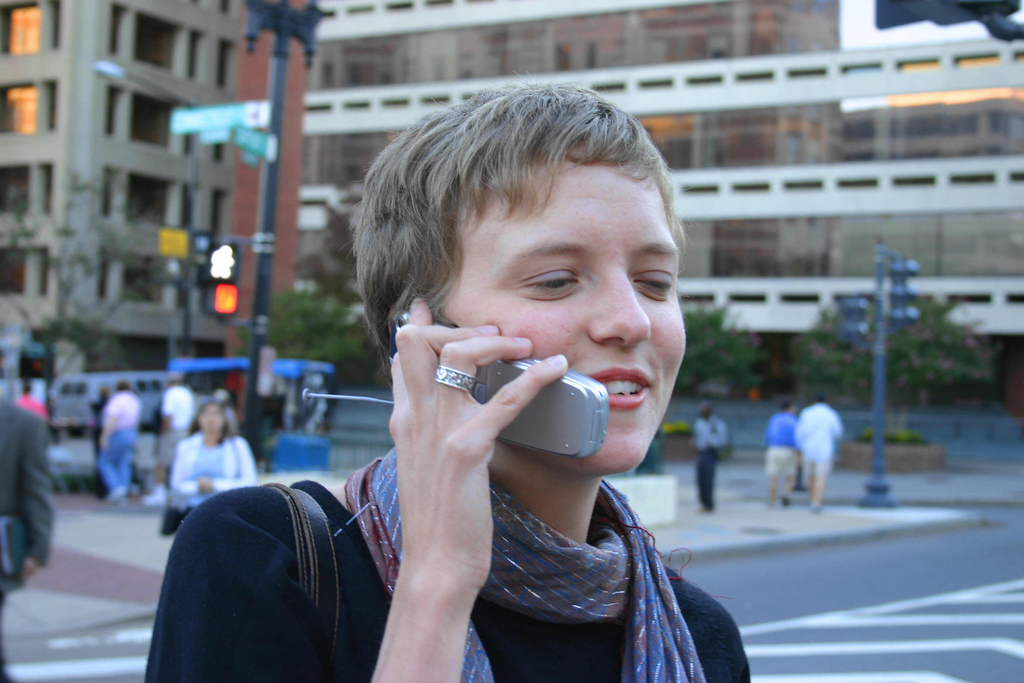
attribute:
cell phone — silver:
[386, 301, 635, 483]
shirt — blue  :
[764, 411, 808, 448]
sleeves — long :
[136, 482, 337, 643]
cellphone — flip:
[464, 360, 635, 479]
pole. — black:
[855, 246, 929, 517]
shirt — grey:
[691, 417, 735, 454]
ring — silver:
[423, 362, 482, 399]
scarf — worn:
[352, 443, 724, 677]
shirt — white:
[794, 403, 847, 492]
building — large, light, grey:
[25, 65, 246, 411]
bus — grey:
[70, 340, 185, 427]